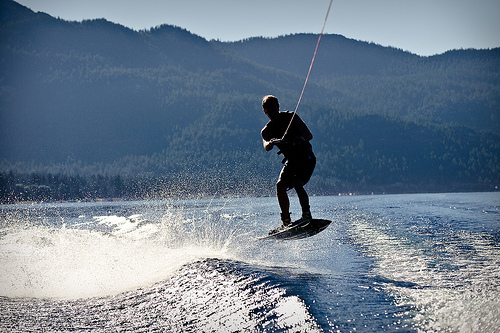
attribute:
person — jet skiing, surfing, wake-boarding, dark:
[253, 87, 322, 231]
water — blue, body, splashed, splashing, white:
[2, 184, 498, 331]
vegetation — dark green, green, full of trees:
[2, 6, 500, 192]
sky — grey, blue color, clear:
[23, 0, 500, 50]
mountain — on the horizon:
[9, 6, 500, 195]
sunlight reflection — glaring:
[434, 201, 493, 213]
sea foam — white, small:
[11, 192, 260, 302]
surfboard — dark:
[261, 218, 334, 243]